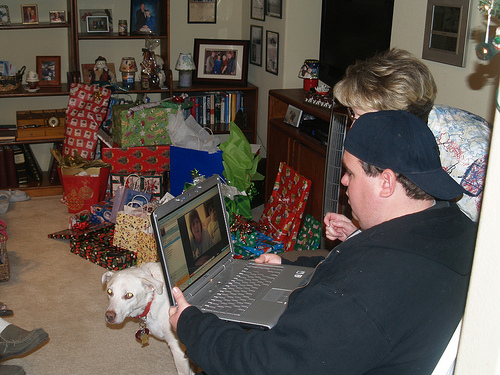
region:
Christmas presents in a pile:
[59, 72, 250, 271]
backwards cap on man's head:
[336, 106, 463, 215]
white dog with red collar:
[79, 254, 196, 362]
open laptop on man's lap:
[146, 164, 303, 329]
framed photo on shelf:
[179, 30, 261, 92]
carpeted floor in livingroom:
[31, 258, 108, 343]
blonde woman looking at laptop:
[325, 47, 484, 187]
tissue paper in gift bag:
[159, 110, 224, 169]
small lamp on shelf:
[169, 48, 205, 93]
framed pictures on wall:
[236, 7, 299, 89]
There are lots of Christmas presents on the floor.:
[64, 84, 302, 281]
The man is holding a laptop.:
[128, 182, 315, 344]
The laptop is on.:
[139, 171, 321, 347]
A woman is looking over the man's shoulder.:
[329, 48, 486, 222]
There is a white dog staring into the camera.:
[83, 257, 190, 372]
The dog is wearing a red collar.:
[96, 265, 167, 356]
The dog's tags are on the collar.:
[131, 273, 158, 353]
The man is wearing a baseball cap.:
[339, 106, 469, 209]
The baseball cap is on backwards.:
[341, 103, 477, 205]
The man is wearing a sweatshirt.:
[173, 195, 485, 374]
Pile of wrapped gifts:
[74, 86, 218, 174]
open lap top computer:
[121, 174, 313, 319]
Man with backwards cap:
[337, 111, 471, 205]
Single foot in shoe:
[0, 313, 64, 365]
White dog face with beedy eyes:
[81, 270, 171, 352]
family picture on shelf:
[194, 43, 254, 82]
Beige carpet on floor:
[18, 213, 56, 306]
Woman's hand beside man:
[317, 210, 354, 245]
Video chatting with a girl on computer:
[182, 204, 237, 244]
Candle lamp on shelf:
[172, 52, 198, 86]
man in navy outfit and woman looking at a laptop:
[150, 49, 458, 362]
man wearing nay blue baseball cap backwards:
[340, 108, 460, 245]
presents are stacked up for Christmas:
[69, 81, 154, 259]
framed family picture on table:
[182, 31, 258, 89]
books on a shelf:
[167, 86, 244, 134]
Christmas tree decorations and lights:
[470, 0, 498, 87]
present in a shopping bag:
[164, 114, 223, 176]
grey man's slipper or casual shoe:
[0, 251, 63, 361]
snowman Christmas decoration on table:
[291, 59, 331, 94]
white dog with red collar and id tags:
[80, 255, 182, 370]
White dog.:
[99, 268, 157, 328]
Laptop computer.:
[150, 193, 315, 326]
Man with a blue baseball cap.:
[329, 110, 474, 366]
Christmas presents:
[49, 80, 270, 184]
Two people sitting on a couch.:
[291, 44, 468, 364]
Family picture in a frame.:
[194, 38, 245, 80]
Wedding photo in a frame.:
[130, 1, 165, 32]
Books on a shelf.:
[185, 85, 253, 130]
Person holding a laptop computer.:
[175, 120, 466, 368]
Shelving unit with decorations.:
[2, 2, 252, 90]